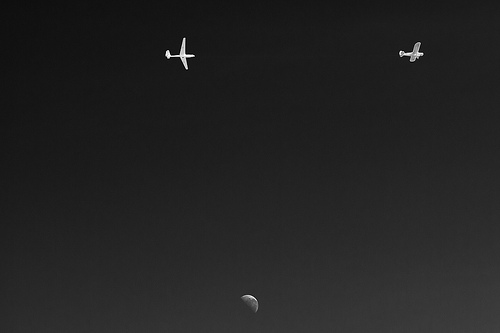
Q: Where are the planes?
A: In the sky.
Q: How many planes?
A: 2.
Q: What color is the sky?
A: Black.